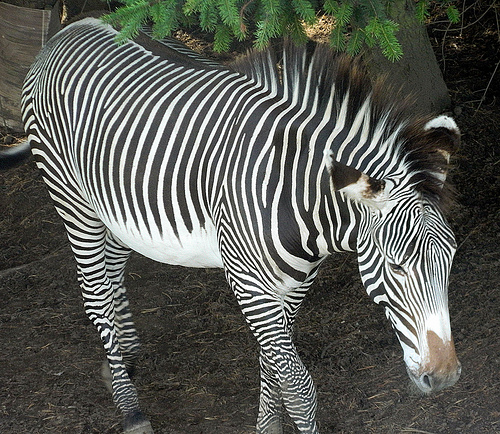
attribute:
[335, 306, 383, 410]
dirt — gray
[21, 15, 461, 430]
zebra — black, white, striped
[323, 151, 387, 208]
ear — curled down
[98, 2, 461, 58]
trees — green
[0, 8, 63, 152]
post — wooden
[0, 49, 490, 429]
area — grassy